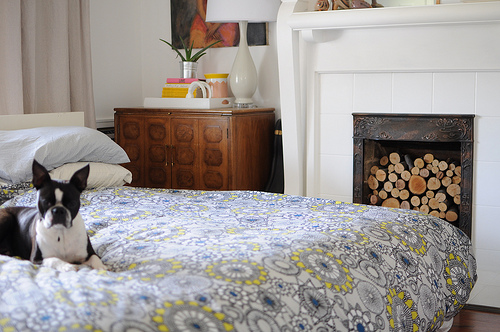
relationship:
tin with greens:
[184, 60, 195, 78] [161, 31, 220, 62]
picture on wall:
[170, 2, 268, 48] [112, 2, 283, 121]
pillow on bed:
[1, 128, 132, 183] [0, 111, 476, 331]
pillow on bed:
[41, 163, 137, 191] [0, 111, 476, 331]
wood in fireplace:
[369, 151, 461, 221] [275, 4, 500, 281]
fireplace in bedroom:
[275, 4, 500, 281] [0, 0, 499, 331]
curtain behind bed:
[0, 0, 100, 131] [0, 111, 476, 331]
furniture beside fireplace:
[115, 109, 275, 188] [275, 4, 500, 281]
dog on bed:
[1, 158, 108, 273] [0, 111, 476, 331]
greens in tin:
[161, 31, 220, 62] [184, 60, 195, 78]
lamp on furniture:
[205, 0, 280, 108] [115, 109, 275, 188]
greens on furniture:
[161, 31, 220, 62] [115, 109, 275, 188]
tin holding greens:
[184, 60, 195, 78] [161, 31, 220, 62]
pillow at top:
[1, 128, 132, 183] [0, 112, 84, 129]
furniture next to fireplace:
[115, 109, 275, 188] [275, 4, 500, 281]